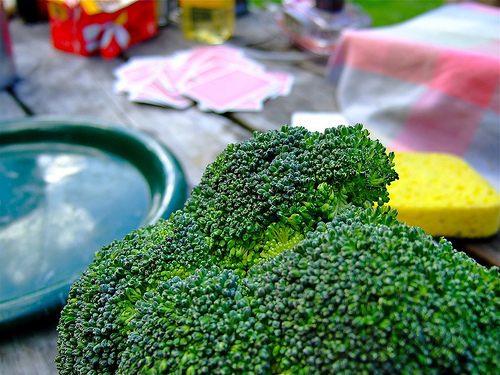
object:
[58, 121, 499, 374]
broccoli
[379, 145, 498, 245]
sponge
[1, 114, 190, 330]
plate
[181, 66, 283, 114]
cards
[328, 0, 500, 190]
cloth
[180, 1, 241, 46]
liquid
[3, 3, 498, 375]
table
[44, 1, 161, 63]
box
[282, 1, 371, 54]
bottle